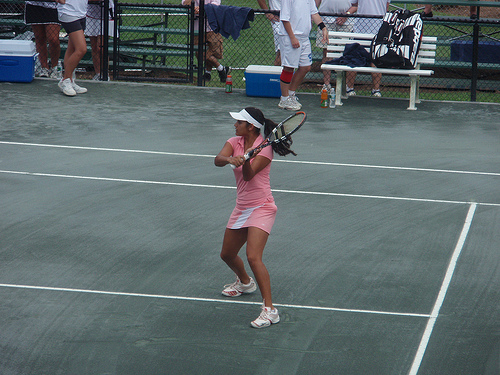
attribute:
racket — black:
[270, 112, 318, 151]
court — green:
[96, 160, 184, 283]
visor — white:
[223, 108, 264, 126]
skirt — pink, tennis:
[228, 209, 261, 238]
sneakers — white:
[247, 306, 297, 328]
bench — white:
[333, 23, 437, 107]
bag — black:
[339, 39, 376, 74]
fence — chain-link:
[212, 15, 240, 87]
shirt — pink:
[230, 138, 280, 194]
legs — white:
[404, 72, 426, 122]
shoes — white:
[216, 270, 261, 309]